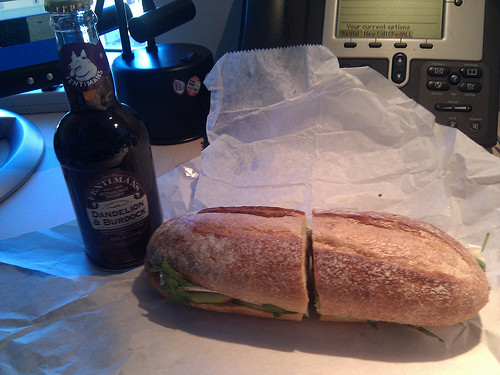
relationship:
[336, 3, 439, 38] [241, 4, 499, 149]
screen on phone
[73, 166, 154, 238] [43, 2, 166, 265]
label on bottle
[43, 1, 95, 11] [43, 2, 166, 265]
cap on bottle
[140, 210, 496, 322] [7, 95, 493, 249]
sandwich on desk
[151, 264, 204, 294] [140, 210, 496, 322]
lettuce in sandwich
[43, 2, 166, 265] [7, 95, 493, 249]
bottle on desk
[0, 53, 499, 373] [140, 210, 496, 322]
wrapper under sandwich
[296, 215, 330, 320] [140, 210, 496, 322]
line on sandwich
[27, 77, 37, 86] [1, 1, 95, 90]
knob on monitor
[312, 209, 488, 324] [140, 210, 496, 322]
bread on sandwich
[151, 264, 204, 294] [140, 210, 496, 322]
lettuce on sandwich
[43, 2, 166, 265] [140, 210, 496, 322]
bottle next to sandwich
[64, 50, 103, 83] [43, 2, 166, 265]
dog on bottle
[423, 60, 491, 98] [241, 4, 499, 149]
buttons on phone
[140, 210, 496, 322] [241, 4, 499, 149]
sandwich in front of phone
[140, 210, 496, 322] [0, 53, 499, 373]
sandwich on wrapper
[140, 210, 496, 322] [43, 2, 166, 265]
sandwich next to bottle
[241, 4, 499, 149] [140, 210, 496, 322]
phone behind sandwich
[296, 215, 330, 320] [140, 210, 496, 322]
cleft of sandwich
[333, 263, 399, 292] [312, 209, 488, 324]
flour on bread